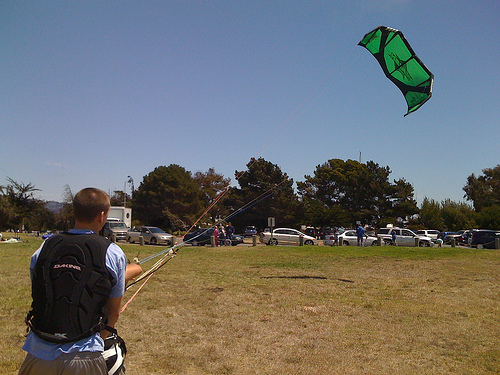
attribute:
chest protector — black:
[25, 232, 118, 344]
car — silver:
[260, 226, 317, 245]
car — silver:
[324, 229, 379, 246]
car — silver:
[374, 228, 433, 245]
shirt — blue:
[23, 230, 126, 361]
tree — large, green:
[296, 159, 419, 236]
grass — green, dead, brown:
[0, 232, 499, 374]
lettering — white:
[53, 264, 82, 271]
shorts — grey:
[18, 353, 109, 375]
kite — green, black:
[358, 24, 435, 117]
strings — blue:
[122, 44, 405, 315]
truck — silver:
[108, 206, 133, 230]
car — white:
[418, 230, 441, 239]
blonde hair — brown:
[74, 187, 111, 223]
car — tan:
[125, 227, 175, 245]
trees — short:
[418, 196, 500, 231]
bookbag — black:
[100, 336, 124, 374]